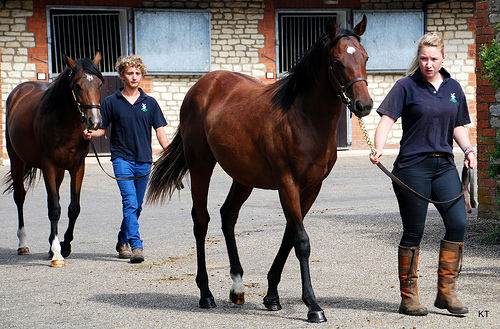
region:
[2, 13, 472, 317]
Two people leading horses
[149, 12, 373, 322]
A horse with a white spot on its head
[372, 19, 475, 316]
A young girl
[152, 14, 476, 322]
A young girl walking a horse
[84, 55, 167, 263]
A young boy with blonde hair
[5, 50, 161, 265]
A young boy leading a horse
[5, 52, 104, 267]
A brown horse with a dark mane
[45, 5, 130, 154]
A horse stall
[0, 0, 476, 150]
A bricked building with horse stalls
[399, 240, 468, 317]
A pair of brown and orange work boots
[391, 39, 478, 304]
a very sexy blonde girl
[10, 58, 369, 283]
a couple of brown horses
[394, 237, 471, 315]
a girl wearing a couple of boots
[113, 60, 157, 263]
a boy guiding the horse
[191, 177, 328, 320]
the four legs of the horse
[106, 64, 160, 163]
the man in a blue sweater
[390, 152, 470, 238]
a girl wearing sexy pants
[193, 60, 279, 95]
the back of the brown horse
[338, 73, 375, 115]
the girl holding the horse break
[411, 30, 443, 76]
the blonde girl head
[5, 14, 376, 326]
two dark brown horses with white spots on their foreheads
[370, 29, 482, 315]
a woman leads a horse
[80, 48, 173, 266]
a man leading a horse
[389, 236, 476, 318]
brown boots worn by woman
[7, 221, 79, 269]
two white "socks" on horse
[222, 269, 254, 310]
one white foot on horse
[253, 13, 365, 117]
black mane on brown horse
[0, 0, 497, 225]
brick building behind two horses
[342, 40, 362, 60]
white spot on brown horse's forehead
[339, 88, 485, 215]
lead hooked to horse's bridle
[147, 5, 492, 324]
The woman is walking a horse.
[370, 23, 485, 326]
The woman is wearing boots.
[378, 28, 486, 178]
The woman has hair.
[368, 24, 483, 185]
The woman's hair is blonde.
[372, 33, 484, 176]
The woman is wearing a shirt.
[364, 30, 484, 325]
The woman is wearing pants.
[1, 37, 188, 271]
The man is walking a horse.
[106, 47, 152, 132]
The man has curly hair.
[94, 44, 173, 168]
The man is wearing a shirt.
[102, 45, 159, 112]
The man's hair is tousled.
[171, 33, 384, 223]
the horse is brown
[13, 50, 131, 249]
the horse is brown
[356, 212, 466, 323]
girl is wearing boots